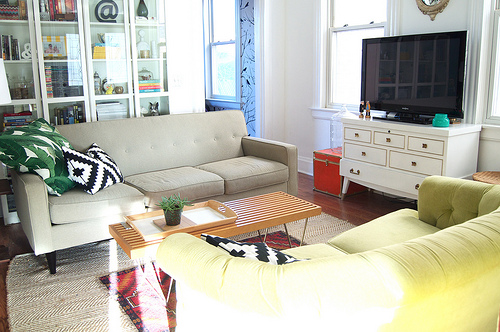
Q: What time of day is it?
A: Day time.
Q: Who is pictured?
A: No one.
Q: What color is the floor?
A: Wood.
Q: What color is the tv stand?
A: White.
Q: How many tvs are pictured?
A: One.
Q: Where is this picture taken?
A: Living room.